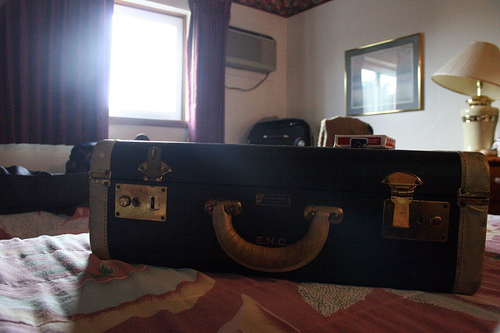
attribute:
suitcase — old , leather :
[90, 139, 487, 297]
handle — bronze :
[203, 196, 345, 273]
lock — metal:
[108, 183, 179, 214]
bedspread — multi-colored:
[0, 217, 499, 329]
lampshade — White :
[398, 40, 496, 122]